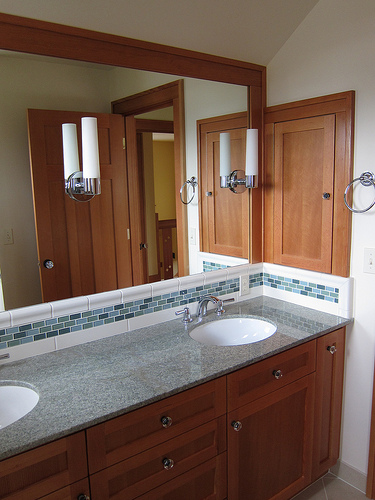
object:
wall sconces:
[230, 124, 259, 194]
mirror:
[0, 51, 250, 284]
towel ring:
[342, 175, 375, 215]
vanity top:
[3, 297, 354, 454]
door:
[20, 111, 128, 302]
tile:
[8, 264, 348, 344]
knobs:
[324, 344, 339, 356]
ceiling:
[49, 0, 312, 68]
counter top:
[0, 312, 268, 402]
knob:
[272, 368, 284, 380]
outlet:
[0, 352, 10, 362]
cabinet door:
[273, 114, 336, 274]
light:
[240, 129, 261, 193]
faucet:
[174, 294, 225, 324]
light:
[76, 113, 103, 199]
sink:
[187, 313, 274, 348]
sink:
[0, 375, 40, 428]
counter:
[0, 292, 349, 459]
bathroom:
[3, 0, 372, 496]